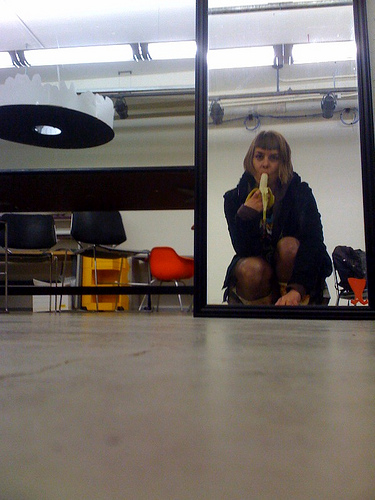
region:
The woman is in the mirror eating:
[215, 126, 350, 322]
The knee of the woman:
[232, 256, 265, 295]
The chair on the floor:
[64, 208, 157, 316]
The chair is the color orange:
[143, 243, 195, 293]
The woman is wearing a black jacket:
[225, 167, 334, 290]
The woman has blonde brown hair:
[242, 124, 304, 189]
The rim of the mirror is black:
[187, 18, 222, 315]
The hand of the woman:
[271, 287, 305, 309]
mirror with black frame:
[192, 2, 372, 317]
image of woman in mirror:
[224, 128, 329, 305]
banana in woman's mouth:
[245, 130, 290, 219]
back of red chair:
[137, 246, 195, 311]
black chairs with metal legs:
[1, 210, 152, 310]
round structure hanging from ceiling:
[1, 75, 117, 148]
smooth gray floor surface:
[1, 311, 372, 496]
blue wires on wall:
[236, 107, 358, 132]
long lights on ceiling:
[2, 40, 195, 66]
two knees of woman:
[231, 236, 300, 305]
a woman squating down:
[223, 130, 333, 306]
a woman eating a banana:
[223, 130, 332, 305]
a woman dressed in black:
[223, 128, 333, 303]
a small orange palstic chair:
[142, 244, 193, 280]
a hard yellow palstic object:
[80, 251, 133, 313]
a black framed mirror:
[194, 0, 374, 319]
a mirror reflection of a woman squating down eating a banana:
[207, 126, 365, 306]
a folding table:
[3, 169, 194, 209]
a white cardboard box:
[32, 277, 74, 312]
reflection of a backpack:
[332, 244, 368, 287]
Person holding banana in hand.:
[250, 183, 280, 214]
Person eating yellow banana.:
[254, 166, 274, 184]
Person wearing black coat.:
[298, 193, 330, 254]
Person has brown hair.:
[252, 127, 294, 164]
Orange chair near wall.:
[150, 245, 193, 269]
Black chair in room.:
[69, 217, 118, 260]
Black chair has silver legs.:
[85, 260, 173, 294]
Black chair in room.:
[13, 223, 46, 247]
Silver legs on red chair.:
[145, 278, 192, 308]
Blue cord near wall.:
[241, 107, 272, 127]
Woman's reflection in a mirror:
[191, 50, 371, 329]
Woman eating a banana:
[215, 127, 337, 305]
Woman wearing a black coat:
[220, 133, 336, 298]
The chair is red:
[139, 242, 193, 288]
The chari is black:
[64, 213, 150, 269]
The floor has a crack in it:
[2, 337, 169, 391]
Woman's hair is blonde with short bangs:
[238, 128, 298, 173]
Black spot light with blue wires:
[311, 86, 350, 126]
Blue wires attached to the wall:
[228, 110, 286, 124]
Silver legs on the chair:
[142, 276, 189, 315]